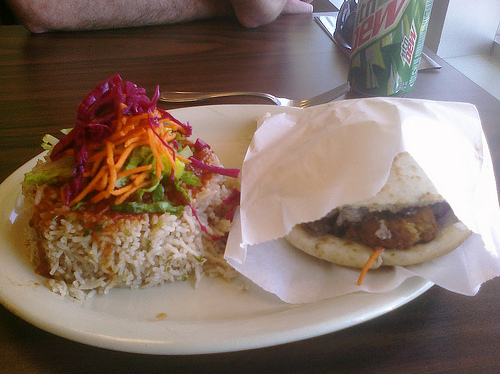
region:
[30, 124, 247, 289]
the meal has rice in it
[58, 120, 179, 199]
carrots have been thinly sliced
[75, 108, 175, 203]
the carrots are orange in color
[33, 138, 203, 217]
the lettuce is thinly sliced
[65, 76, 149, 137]
the meal has red cabbage in it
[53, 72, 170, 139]
the cabbage is red in color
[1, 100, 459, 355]
the meal is on a plate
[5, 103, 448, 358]
the plate is white in color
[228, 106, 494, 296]
the meal is inside a bag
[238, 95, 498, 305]
the bag is white in color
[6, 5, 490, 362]
Picture is taken indoors.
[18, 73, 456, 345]
The plate is white.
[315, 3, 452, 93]
A can of Mountain Dew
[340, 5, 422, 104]
The soda is on the table.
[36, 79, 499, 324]
The plate on the table is white.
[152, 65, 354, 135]
A fork is on the table.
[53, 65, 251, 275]
There are carrots on top of the rice.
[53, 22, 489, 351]
The picture is taken indoors.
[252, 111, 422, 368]
A hamburger is inside a paper work.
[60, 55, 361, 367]
The table is made of wood.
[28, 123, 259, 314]
vegetable on rice patty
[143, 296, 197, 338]
brown crumbs on plate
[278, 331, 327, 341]
shiny edge of white plate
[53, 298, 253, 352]
portion of white plate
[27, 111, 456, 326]
large white plate with food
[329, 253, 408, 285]
small piece of orange carrot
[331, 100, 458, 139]
crinkles in white paper bag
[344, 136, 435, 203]
edge of paper bag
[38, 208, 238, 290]
white rice on the plate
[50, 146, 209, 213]
green lettuce on the plate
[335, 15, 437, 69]
green and white soda can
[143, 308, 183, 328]
small bit of crumb on white plate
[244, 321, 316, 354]
shiny edge of white plate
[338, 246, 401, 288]
single slice of orange carrot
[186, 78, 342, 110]
long silver fork on table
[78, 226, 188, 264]
white rice on plate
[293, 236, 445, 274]
white bun in paper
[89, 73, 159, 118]
purple vegetable on plate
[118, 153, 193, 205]
slivers of green lettuce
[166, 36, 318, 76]
dark brown table